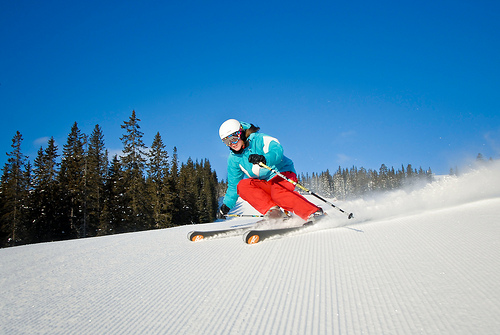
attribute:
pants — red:
[235, 171, 321, 222]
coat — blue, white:
[217, 132, 301, 211]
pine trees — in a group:
[1, 106, 226, 251]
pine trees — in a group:
[292, 160, 439, 197]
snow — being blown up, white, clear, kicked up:
[317, 157, 500, 233]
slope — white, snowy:
[3, 162, 499, 334]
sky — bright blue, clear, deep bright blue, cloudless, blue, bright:
[1, 0, 497, 172]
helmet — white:
[217, 117, 242, 140]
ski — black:
[186, 211, 273, 244]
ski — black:
[243, 218, 319, 246]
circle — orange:
[190, 232, 206, 243]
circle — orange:
[245, 230, 262, 247]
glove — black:
[247, 151, 268, 167]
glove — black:
[212, 202, 232, 222]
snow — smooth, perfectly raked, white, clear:
[0, 159, 499, 334]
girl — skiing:
[211, 117, 329, 229]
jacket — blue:
[220, 133, 299, 212]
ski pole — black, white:
[256, 160, 357, 222]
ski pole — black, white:
[219, 211, 266, 221]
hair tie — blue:
[238, 118, 251, 133]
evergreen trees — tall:
[0, 103, 228, 250]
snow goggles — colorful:
[221, 129, 243, 147]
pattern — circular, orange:
[190, 228, 207, 244]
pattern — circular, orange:
[245, 230, 261, 246]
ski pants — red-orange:
[236, 171, 322, 220]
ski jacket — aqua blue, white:
[218, 132, 297, 210]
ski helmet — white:
[217, 115, 243, 140]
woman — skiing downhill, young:
[218, 116, 328, 226]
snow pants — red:
[233, 171, 322, 218]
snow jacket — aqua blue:
[220, 130, 298, 208]